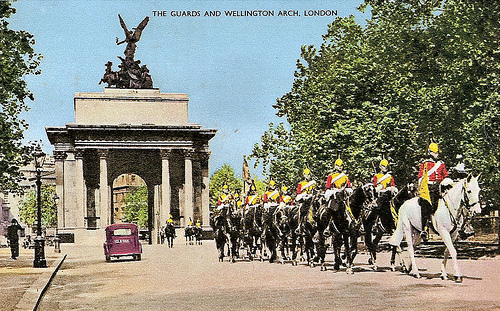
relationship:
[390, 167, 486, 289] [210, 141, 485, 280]
horse leading pack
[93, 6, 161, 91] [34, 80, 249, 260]
statue on top of stone structue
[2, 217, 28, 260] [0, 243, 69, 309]
man walking down sidewalk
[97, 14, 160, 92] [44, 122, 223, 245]
statue on top of doorway